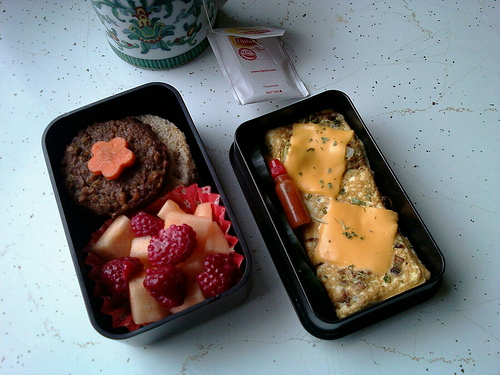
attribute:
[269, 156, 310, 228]
bottle — small, red, plastic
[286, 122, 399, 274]
cheese — sliced, melted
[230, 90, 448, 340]
pan — black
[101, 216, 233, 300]
berries — red, sliced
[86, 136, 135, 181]
carrot — sliced, orange, flower shaped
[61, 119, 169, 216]
hamburger — pattied, cooked